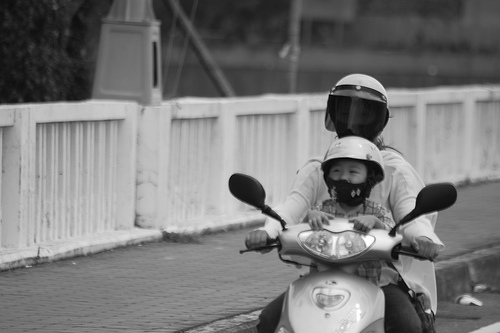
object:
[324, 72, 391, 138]
full helmet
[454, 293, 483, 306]
trash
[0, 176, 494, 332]
ground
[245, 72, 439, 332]
mother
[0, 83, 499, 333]
bridge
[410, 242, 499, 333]
road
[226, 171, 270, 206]
mirror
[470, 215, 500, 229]
brick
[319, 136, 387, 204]
helmet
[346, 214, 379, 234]
hands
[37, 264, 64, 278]
brick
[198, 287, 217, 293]
brick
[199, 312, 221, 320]
brick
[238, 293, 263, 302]
brick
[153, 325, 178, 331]
brick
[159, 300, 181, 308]
brick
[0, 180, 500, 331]
sidewalk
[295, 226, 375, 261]
headlight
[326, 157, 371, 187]
face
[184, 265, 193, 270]
brick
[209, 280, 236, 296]
brick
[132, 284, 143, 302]
brick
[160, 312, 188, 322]
brick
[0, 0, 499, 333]
image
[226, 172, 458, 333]
scooter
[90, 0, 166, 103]
pole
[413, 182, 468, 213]
mirror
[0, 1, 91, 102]
tree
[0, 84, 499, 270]
bridge railing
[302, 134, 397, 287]
boy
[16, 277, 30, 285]
brick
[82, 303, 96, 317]
brick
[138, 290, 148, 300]
brick